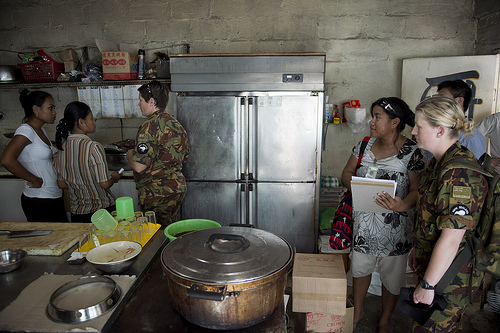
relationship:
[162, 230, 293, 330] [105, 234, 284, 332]
pot sitting on stove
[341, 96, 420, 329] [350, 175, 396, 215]
woman holding note pad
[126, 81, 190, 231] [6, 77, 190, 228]
soldier getting cooking lessons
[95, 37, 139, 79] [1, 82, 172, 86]
box on a shelf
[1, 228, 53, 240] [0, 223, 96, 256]
knife on cutting board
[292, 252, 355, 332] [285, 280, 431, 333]
boxes stacked on floor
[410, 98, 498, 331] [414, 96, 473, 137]
woman with blonde hair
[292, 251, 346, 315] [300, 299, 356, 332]
box stacked on box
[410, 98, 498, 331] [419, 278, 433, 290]
woman has wrist watch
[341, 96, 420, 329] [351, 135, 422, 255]
woman with black and white top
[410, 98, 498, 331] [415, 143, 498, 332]
person wearing camoflauge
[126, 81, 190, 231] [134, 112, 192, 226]
woman wearing camoflauge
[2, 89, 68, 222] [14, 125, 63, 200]
woman wearing white t-shirt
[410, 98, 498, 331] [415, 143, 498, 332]
woman in army uniform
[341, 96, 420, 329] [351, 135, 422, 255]
woman in black and white top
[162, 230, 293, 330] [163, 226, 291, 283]
cooking pot with lid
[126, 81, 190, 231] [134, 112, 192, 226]
woman in army uniform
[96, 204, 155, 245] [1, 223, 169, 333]
glasses on counter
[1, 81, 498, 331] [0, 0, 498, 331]
people standing in kitchen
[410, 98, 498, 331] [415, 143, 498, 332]
woman in camouflage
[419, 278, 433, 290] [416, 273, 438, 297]
watch on wrist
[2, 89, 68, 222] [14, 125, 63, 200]
woman with white top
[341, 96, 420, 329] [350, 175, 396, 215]
woman holding tablet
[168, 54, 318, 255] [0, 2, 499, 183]
refrigerator against wall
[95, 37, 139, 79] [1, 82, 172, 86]
box on shelf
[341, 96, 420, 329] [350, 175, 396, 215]
woman holding paper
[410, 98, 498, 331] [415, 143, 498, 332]
woman in camoflauge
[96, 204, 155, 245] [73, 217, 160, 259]
cups on tray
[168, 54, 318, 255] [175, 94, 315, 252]
refrigerator with double door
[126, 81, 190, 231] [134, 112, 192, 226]
woman in camoflauge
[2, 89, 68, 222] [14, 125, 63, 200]
woman in white t-shirt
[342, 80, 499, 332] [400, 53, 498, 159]
people standing near door